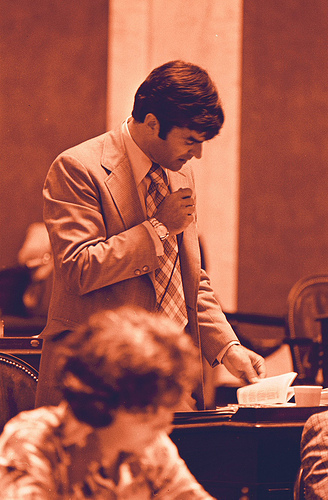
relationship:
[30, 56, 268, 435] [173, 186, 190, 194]
man speaking into microphone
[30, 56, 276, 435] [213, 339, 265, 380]
man has hand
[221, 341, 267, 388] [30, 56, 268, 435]
hand of man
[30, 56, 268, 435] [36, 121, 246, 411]
man wearing a suit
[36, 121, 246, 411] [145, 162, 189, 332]
suit and tie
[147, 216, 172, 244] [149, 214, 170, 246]
watch on wrist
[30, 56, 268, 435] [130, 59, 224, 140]
man has hair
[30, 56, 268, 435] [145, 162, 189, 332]
man has tie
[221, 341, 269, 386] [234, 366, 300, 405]
hand turning page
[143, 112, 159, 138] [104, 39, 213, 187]
ear on head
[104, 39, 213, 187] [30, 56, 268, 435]
head of man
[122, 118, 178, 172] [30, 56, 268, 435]
neck of man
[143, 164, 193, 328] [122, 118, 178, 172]
tie around neck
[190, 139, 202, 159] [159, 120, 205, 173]
nose on face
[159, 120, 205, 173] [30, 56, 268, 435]
face of man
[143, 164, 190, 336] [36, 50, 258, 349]
tie on man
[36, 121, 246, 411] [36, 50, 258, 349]
suit on man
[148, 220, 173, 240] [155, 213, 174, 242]
watch on wrist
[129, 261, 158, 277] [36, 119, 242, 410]
two buttons are on suit